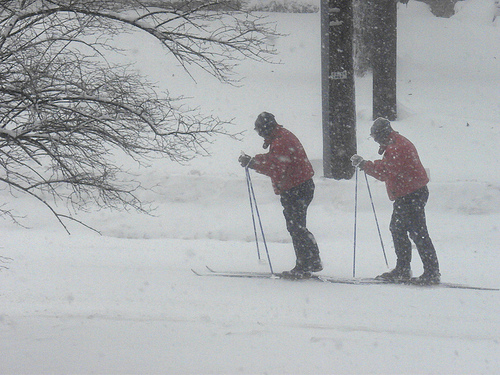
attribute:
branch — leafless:
[1, 173, 103, 250]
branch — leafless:
[16, 163, 161, 227]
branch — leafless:
[1, 110, 193, 177]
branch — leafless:
[5, 75, 249, 165]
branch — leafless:
[1, 2, 286, 94]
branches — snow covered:
[1, 3, 288, 233]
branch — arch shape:
[37, 70, 192, 136]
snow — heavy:
[41, 253, 202, 355]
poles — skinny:
[350, 171, 357, 282]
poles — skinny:
[363, 176, 390, 276]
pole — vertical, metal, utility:
[309, 0, 371, 189]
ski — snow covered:
[186, 267, 355, 281]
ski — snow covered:
[201, 263, 307, 276]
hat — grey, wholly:
[255, 108, 282, 132]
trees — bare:
[18, 22, 238, 222]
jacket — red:
[254, 138, 319, 196]